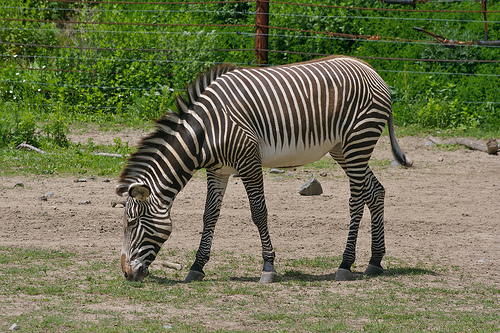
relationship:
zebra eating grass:
[85, 51, 432, 283] [1, 243, 499, 329]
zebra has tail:
[85, 51, 432, 283] [384, 101, 421, 172]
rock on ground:
[294, 174, 330, 197] [1, 118, 497, 332]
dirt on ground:
[8, 177, 499, 260] [1, 118, 497, 332]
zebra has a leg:
[85, 51, 432, 283] [183, 166, 234, 289]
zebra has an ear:
[85, 51, 432, 283] [115, 178, 156, 204]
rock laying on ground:
[294, 174, 330, 197] [1, 118, 497, 332]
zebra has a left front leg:
[85, 51, 432, 283] [227, 147, 296, 292]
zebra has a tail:
[85, 51, 432, 283] [384, 101, 421, 172]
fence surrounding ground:
[1, 1, 499, 171] [1, 118, 497, 332]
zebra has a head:
[85, 51, 432, 283] [106, 182, 181, 283]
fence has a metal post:
[0, 0, 498, 131] [251, 0, 275, 65]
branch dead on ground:
[12, 137, 138, 165] [1, 118, 497, 332]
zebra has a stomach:
[85, 51, 432, 283] [256, 135, 347, 166]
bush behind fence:
[1, 1, 499, 171] [0, 0, 498, 131]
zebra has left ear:
[85, 51, 432, 283] [129, 181, 154, 201]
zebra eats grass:
[85, 51, 432, 283] [1, 243, 499, 329]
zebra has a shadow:
[85, 51, 432, 283] [154, 271, 428, 284]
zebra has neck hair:
[85, 51, 432, 283] [105, 115, 171, 190]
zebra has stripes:
[85, 51, 432, 283] [217, 76, 373, 146]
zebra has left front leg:
[85, 51, 432, 283] [227, 147, 296, 292]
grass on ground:
[1, 243, 499, 329] [1, 118, 497, 332]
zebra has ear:
[85, 51, 432, 283] [115, 178, 156, 204]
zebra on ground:
[85, 51, 432, 283] [1, 118, 497, 332]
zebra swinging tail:
[85, 51, 432, 283] [384, 101, 421, 172]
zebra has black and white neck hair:
[85, 51, 432, 283] [105, 115, 171, 190]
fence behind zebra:
[0, 0, 498, 131] [85, 51, 432, 283]